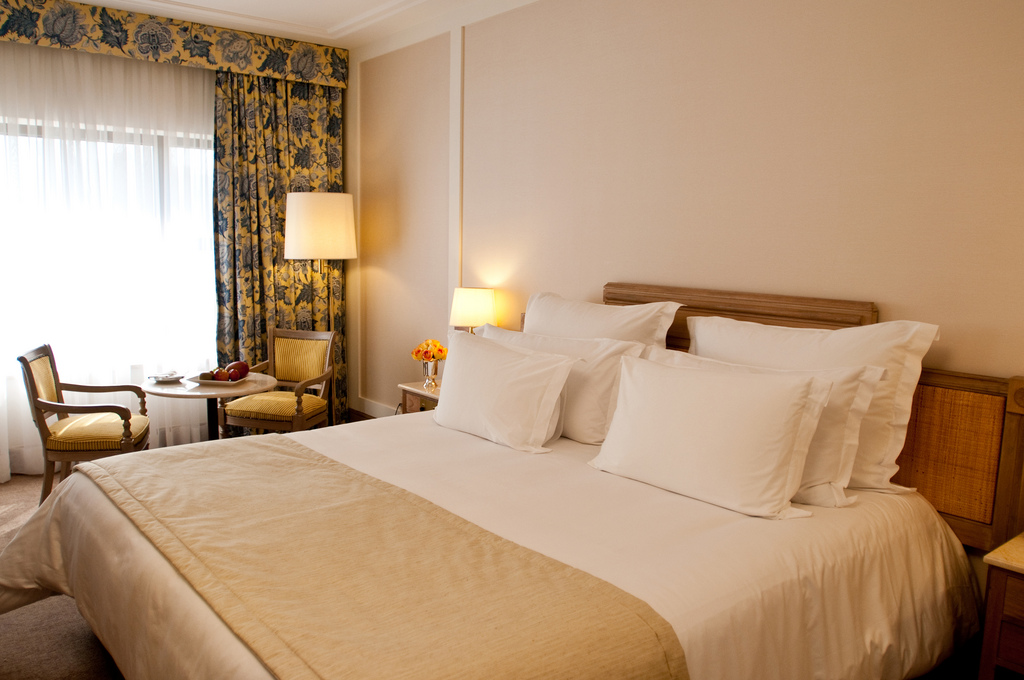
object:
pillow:
[429, 328, 579, 454]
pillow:
[518, 286, 687, 360]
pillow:
[584, 352, 838, 523]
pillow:
[681, 315, 939, 494]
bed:
[2, 278, 1021, 680]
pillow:
[641, 341, 890, 510]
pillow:
[466, 319, 653, 451]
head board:
[599, 282, 1024, 553]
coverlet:
[69, 406, 989, 680]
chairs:
[217, 326, 341, 441]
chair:
[13, 344, 160, 510]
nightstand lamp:
[446, 286, 501, 336]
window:
[0, 126, 234, 400]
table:
[137, 366, 280, 446]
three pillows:
[584, 314, 938, 521]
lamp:
[282, 190, 359, 426]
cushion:
[46, 412, 159, 445]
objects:
[147, 370, 185, 383]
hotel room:
[2, 1, 1023, 680]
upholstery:
[28, 354, 61, 413]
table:
[397, 378, 444, 415]